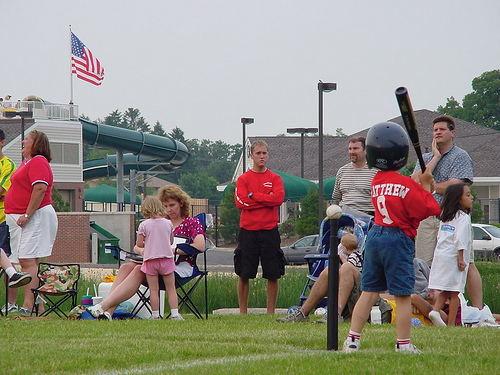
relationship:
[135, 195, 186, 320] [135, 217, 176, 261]
girl wearing shirt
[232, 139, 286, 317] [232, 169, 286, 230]
boy wearing shirt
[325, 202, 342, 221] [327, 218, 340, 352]
baseball on t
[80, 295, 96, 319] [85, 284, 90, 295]
cup with straw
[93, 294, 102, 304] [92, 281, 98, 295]
cup with straw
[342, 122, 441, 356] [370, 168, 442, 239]
boy wearing shirt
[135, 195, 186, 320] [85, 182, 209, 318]
girl talking to mother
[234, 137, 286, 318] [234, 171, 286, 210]
man has arms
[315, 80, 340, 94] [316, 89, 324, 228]
street light has pole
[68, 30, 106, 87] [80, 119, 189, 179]
flag on top of water slide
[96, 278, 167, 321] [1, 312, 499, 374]
water cooler on grass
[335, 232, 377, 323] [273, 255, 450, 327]
baby standing on father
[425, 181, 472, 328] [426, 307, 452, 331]
girl wearing socks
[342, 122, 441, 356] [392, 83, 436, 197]
boy has bat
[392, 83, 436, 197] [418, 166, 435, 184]
bat in hand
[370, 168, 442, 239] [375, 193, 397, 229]
shirt has 9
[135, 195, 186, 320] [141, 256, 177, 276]
girl wearing shorts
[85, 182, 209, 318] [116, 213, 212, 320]
mother sitting in chair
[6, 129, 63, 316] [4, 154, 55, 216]
woman wearing shirt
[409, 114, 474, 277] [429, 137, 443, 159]
man has hand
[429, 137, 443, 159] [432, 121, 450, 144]
hand on face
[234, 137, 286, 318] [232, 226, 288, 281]
man wearing shorts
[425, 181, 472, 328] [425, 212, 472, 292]
girl wearing tee shirt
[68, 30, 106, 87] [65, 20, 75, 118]
flag on pole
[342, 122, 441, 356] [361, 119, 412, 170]
boy wearing helmet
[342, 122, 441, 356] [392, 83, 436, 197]
boy holding bat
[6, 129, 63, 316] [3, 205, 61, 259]
woman wearing shorts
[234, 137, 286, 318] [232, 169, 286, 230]
man wearing shirt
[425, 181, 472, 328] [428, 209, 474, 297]
girl wearing shirt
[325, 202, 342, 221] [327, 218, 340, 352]
baseball on tee ball stand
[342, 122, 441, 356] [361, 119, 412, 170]
kid wearing helmet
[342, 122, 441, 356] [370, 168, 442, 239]
kid wearing shirt